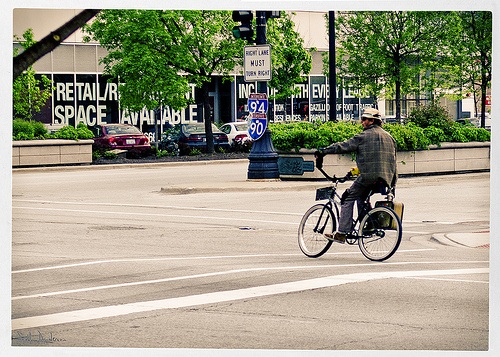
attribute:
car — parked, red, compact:
[90, 123, 151, 162]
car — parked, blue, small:
[153, 120, 230, 157]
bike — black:
[299, 149, 403, 266]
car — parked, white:
[217, 121, 268, 149]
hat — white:
[361, 106, 381, 120]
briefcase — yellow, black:
[373, 201, 404, 231]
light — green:
[232, 28, 242, 38]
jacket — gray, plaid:
[319, 125, 402, 200]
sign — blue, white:
[247, 92, 269, 119]